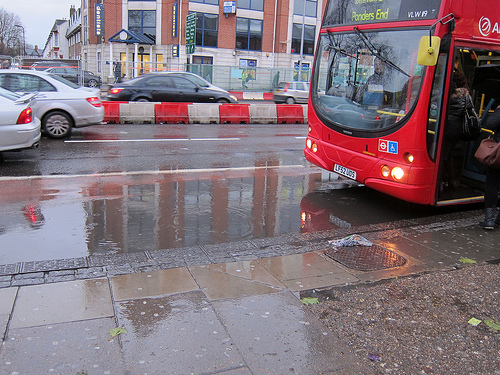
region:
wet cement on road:
[42, 182, 69, 213]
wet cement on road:
[122, 185, 158, 220]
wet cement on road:
[182, 190, 207, 225]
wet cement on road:
[235, 183, 260, 205]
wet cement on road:
[291, 165, 315, 195]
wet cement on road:
[318, 194, 339, 227]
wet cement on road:
[268, 211, 294, 233]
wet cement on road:
[246, 207, 269, 225]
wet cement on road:
[237, 220, 274, 247]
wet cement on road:
[199, 218, 224, 245]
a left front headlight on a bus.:
[384, 160, 416, 190]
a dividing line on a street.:
[0, 162, 310, 185]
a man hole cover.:
[309, 236, 419, 282]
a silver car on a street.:
[1, 72, 46, 167]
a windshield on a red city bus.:
[310, 24, 443, 138]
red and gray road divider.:
[99, 96, 321, 131]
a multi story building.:
[81, 0, 323, 96]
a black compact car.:
[110, 70, 238, 108]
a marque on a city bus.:
[341, 1, 401, 21]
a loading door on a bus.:
[438, 35, 495, 199]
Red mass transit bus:
[304, 0, 498, 207]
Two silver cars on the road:
[0, 66, 105, 158]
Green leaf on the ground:
[107, 319, 130, 341]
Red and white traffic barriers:
[95, 96, 310, 124]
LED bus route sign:
[342, 0, 403, 21]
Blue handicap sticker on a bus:
[385, 139, 400, 155]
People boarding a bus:
[443, 40, 498, 232]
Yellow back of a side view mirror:
[415, 33, 442, 68]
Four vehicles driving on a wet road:
[0, 60, 239, 164]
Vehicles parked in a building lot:
[2, 53, 101, 90]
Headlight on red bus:
[388, 163, 408, 183]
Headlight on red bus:
[299, 137, 314, 148]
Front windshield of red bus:
[308, 19, 433, 139]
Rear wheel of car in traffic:
[42, 110, 73, 138]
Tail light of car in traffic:
[12, 106, 36, 122]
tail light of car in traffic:
[79, 98, 104, 108]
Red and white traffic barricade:
[113, 96, 275, 126]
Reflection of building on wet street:
[73, 174, 284, 238]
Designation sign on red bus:
[322, 2, 441, 24]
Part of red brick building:
[219, 20, 232, 47]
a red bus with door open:
[306, 0, 498, 207]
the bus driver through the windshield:
[367, 55, 386, 85]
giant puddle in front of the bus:
[2, 175, 391, 267]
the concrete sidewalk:
[2, 221, 493, 373]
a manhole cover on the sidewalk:
[326, 243, 406, 271]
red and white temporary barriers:
[102, 92, 308, 125]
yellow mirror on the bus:
[417, 35, 439, 63]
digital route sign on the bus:
[348, 0, 394, 22]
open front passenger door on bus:
[435, 35, 498, 202]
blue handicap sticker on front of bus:
[387, 140, 397, 152]